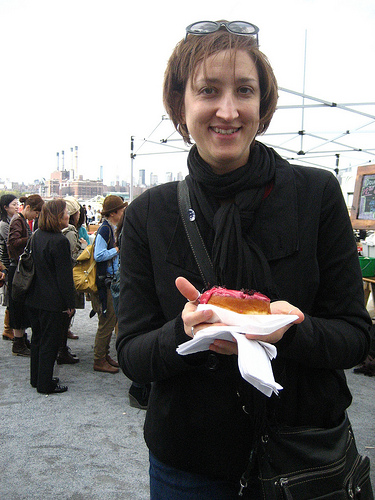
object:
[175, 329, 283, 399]
napkin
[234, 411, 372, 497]
bag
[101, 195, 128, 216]
hat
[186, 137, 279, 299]
scarf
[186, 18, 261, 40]
glass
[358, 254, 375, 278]
bucket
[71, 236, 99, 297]
backpack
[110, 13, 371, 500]
woman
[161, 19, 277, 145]
hair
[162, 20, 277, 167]
head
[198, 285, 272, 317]
dessert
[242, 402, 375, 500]
purse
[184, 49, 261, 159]
face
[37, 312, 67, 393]
pant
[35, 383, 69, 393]
shoe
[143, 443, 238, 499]
jean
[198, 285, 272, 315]
cake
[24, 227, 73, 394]
suit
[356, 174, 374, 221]
chalkboard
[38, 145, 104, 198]
building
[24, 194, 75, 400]
people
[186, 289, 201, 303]
ring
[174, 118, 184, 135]
earring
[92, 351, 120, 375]
boot